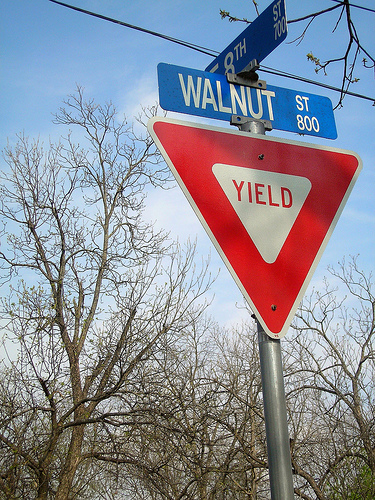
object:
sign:
[145, 0, 363, 500]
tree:
[0, 0, 375, 500]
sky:
[0, 0, 375, 328]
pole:
[255, 323, 291, 499]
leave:
[327, 461, 375, 500]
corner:
[308, 380, 341, 465]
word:
[232, 179, 293, 208]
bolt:
[259, 154, 264, 160]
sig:
[145, 117, 364, 340]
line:
[51, 0, 375, 103]